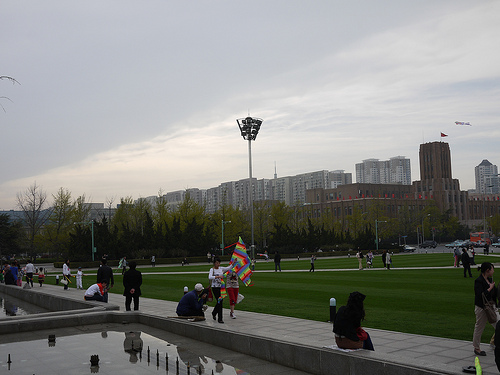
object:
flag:
[433, 109, 485, 140]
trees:
[6, 181, 473, 258]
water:
[1, 299, 24, 317]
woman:
[209, 251, 239, 318]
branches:
[1, 64, 25, 118]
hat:
[192, 282, 206, 292]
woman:
[329, 289, 376, 354]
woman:
[383, 247, 393, 272]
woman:
[37, 265, 46, 285]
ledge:
[200, 320, 280, 347]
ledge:
[291, 339, 491, 374]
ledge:
[3, 305, 77, 321]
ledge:
[116, 307, 145, 316]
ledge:
[72, 298, 119, 308]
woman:
[467, 257, 499, 355]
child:
[74, 267, 83, 287]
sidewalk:
[0, 279, 497, 374]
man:
[174, 281, 211, 321]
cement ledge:
[149, 298, 331, 364]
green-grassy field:
[108, 243, 498, 318]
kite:
[217, 235, 254, 304]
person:
[318, 266, 390, 347]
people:
[5, 252, 144, 310]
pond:
[0, 282, 294, 372]